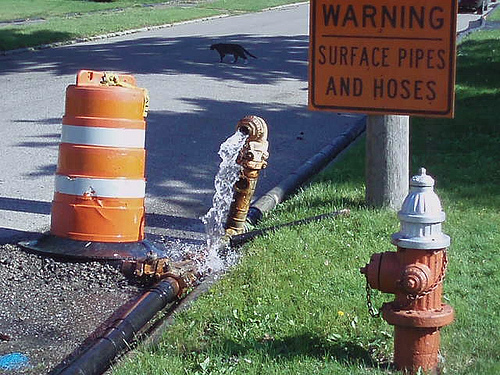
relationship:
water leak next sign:
[196, 108, 275, 268] [303, 2, 460, 124]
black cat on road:
[209, 42, 257, 64] [6, 4, 354, 303]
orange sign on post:
[305, 4, 461, 126] [358, 113, 413, 209]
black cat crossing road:
[209, 42, 257, 64] [0, 0, 492, 375]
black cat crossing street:
[209, 42, 257, 64] [23, 18, 330, 225]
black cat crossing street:
[209, 42, 257, 64] [10, 12, 338, 265]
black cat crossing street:
[209, 42, 257, 64] [5, 12, 334, 289]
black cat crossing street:
[209, 42, 257, 64] [29, 23, 356, 290]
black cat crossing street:
[209, 42, 257, 64] [208, 62, 253, 100]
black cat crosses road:
[209, 42, 257, 64] [73, 49, 318, 162]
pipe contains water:
[221, 112, 269, 234] [198, 126, 248, 272]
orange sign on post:
[304, 0, 460, 115] [366, 113, 412, 211]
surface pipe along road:
[41, 268, 187, 373] [8, 14, 495, 286]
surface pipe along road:
[242, 94, 369, 217] [8, 14, 495, 286]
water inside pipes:
[200, 133, 248, 265] [223, 106, 272, 253]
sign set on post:
[280, 6, 472, 108] [364, 124, 459, 188]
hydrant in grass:
[357, 163, 459, 371] [134, 24, 494, 372]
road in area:
[8, 0, 375, 206] [5, 4, 497, 370]